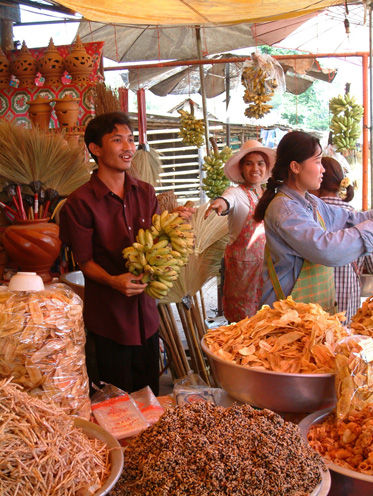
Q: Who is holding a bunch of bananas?
A: The man with the short sleeved shirt.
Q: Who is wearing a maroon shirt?
A: The man holding bananas.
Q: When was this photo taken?
A: During the daytime.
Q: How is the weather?
A: Sunny.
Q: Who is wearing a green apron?
A: The woman wearing a blue shirt.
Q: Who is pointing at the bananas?
A: The woman wearing a hat.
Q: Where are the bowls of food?
A: In front of the people.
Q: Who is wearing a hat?
A: The woman pointing at the bananas.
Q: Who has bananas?
A: The man in maroon.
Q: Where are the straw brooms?
A: Behind the man.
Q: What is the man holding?
A: A bunch of bananas.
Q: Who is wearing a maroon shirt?
A: The man.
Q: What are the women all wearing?
A: Aprons.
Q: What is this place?
A: A market.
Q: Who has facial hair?
A: The man wearing black pants.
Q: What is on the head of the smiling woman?
A: White hat.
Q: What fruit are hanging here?
A: Bananas.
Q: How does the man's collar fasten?
A: Buttons.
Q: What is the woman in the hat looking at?
A: The man.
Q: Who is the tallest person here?
A: The man.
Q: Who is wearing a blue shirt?
A: The woman.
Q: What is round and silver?
A: Bowl.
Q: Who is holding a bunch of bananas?
A: The man.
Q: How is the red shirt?
A: Buttoned up.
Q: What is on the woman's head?
A: Hat.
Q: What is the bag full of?
A: Food.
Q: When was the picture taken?
A: Daytime.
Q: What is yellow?
A: Bananas.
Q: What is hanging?
A: Bunches of bananas.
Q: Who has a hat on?
A: One woman.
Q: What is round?
A: Large bowls.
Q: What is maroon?
A: Man's shirt.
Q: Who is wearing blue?
A: Woman with a ponytail.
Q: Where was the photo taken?
A: In a restaurant.